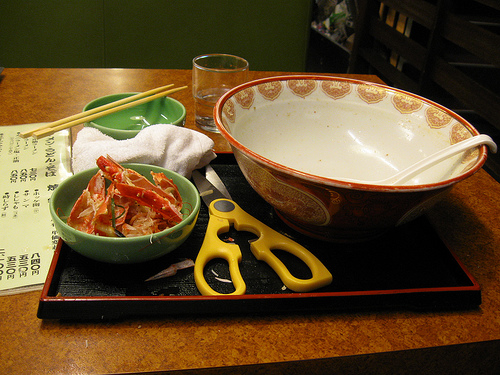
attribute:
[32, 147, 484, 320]
plate — medium size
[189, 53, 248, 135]
glass — Small, half-filled 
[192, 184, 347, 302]
scissors — yellow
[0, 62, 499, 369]
table — pretty, brown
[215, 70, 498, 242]
bowl — white, large, empty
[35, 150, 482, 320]
tray — black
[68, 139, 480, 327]
tray — black, red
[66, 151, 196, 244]
meat — sliced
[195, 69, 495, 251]
bowl — empty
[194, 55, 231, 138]
water glass — clear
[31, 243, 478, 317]
tray — black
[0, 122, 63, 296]
menu — green, laminated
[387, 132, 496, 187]
spoon — ceramic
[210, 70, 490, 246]
soup bowl — ceramic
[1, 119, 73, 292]
menu — red, black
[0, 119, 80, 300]
menu — ethnic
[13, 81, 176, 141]
chopstick — brown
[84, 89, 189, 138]
bowl — small, green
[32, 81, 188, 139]
chopstick — brown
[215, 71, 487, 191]
trim — decorative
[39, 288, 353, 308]
edge — red